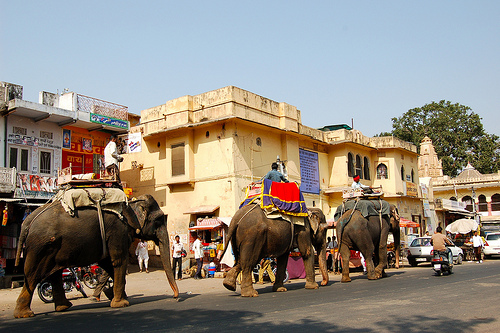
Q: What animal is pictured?
A: Elephants.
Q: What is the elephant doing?
A: Walking.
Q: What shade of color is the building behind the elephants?
A: Tan.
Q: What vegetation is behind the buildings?
A: Trees.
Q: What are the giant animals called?
A: Elephants.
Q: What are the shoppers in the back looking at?
A: The elephants.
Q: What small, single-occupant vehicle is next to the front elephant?
A: A motorcycle.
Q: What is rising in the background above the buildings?
A: Trees.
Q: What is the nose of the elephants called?
A: Trunks.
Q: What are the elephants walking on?
A: A road.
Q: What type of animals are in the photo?
A: Elephants.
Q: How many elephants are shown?
A: Three.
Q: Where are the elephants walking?
A: Street.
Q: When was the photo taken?
A: Daytime.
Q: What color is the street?
A: Gray.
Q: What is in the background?
A: Buildings.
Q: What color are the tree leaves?
A: Green.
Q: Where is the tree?
A: Background.